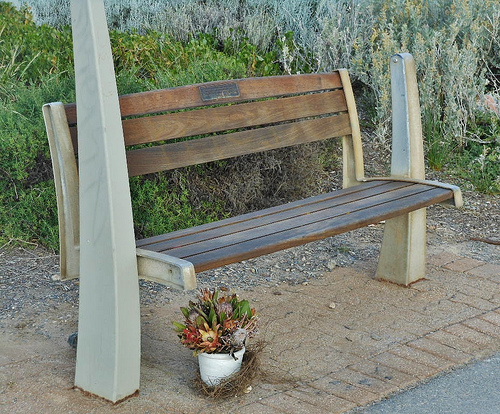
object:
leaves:
[172, 288, 259, 362]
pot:
[277, 316, 390, 384]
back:
[42, 52, 465, 291]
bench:
[43, 53, 464, 291]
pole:
[67, 0, 140, 413]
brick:
[296, 304, 457, 352]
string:
[40, 67, 463, 296]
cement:
[423, 382, 498, 413]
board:
[64, 71, 353, 178]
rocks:
[255, 220, 385, 309]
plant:
[173, 287, 259, 388]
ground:
[0, 133, 500, 414]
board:
[135, 179, 453, 273]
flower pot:
[198, 346, 245, 386]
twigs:
[197, 385, 257, 412]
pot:
[197, 347, 246, 387]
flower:
[171, 288, 256, 360]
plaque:
[196, 79, 241, 103]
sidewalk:
[2, 243, 499, 414]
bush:
[0, 0, 315, 253]